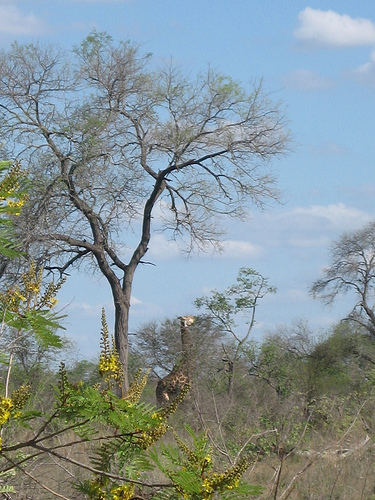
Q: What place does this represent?
A: It represents the field.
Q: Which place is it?
A: It is a field.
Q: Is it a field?
A: Yes, it is a field.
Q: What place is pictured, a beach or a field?
A: It is a field.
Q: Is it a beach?
A: No, it is a field.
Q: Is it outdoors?
A: Yes, it is outdoors.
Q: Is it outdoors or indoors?
A: It is outdoors.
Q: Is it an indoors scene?
A: No, it is outdoors.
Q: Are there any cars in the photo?
A: No, there are no cars.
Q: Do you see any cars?
A: No, there are no cars.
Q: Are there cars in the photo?
A: No, there are no cars.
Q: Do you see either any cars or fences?
A: No, there are no cars or fences.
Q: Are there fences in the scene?
A: No, there are no fences.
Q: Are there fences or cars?
A: No, there are no fences or cars.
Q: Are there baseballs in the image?
A: No, there are no baseballs.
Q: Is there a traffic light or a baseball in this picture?
A: No, there are no baseballs or traffic lights.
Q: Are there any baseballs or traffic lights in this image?
A: No, there are no baseballs or traffic lights.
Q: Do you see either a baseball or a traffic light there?
A: No, there are no baseballs or traffic lights.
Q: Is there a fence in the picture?
A: No, there are no fences.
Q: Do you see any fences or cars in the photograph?
A: No, there are no fences or cars.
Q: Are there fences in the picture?
A: No, there are no fences.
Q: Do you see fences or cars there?
A: No, there are no fences or cars.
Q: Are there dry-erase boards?
A: No, there are no dry-erase boards.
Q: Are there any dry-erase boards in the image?
A: No, there are no dry-erase boards.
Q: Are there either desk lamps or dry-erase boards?
A: No, there are no dry-erase boards or desk lamps.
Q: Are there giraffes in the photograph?
A: Yes, there is a giraffe.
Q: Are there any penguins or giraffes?
A: Yes, there is a giraffe.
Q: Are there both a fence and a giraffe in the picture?
A: No, there is a giraffe but no fences.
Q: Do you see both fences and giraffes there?
A: No, there is a giraffe but no fences.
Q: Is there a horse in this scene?
A: No, there are no horses.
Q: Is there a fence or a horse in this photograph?
A: No, there are no horses or fences.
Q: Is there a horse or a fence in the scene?
A: No, there are no horses or fences.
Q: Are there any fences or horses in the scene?
A: No, there are no horses or fences.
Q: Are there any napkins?
A: No, there are no napkins.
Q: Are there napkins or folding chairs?
A: No, there are no napkins or folding chairs.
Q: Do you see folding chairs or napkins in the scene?
A: No, there are no napkins or folding chairs.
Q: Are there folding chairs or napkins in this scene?
A: No, there are no napkins or folding chairs.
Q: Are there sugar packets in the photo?
A: No, there are no sugar packets.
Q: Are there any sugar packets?
A: No, there are no sugar packets.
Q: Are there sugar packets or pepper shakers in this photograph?
A: No, there are no sugar packets or pepper shakers.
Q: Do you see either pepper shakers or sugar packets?
A: No, there are no sugar packets or pepper shakers.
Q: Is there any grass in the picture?
A: Yes, there is grass.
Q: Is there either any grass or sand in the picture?
A: Yes, there is grass.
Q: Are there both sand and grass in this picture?
A: No, there is grass but no sand.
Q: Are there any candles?
A: No, there are no candles.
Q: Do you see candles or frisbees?
A: No, there are no candles or frisbees.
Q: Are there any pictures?
A: No, there are no pictures.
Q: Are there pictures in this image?
A: No, there are no pictures.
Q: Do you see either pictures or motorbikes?
A: No, there are no pictures or motorbikes.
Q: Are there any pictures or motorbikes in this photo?
A: No, there are no pictures or motorbikes.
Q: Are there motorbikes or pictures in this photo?
A: No, there are no pictures or motorbikes.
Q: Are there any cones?
A: No, there are no cones.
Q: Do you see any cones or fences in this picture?
A: No, there are no cones or fences.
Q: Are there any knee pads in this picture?
A: No, there are no knee pads.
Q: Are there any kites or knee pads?
A: No, there are no knee pads or kites.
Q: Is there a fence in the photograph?
A: No, there are no fences.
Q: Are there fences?
A: No, there are no fences.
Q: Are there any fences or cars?
A: No, there are no fences or cars.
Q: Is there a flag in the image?
A: No, there are no flags.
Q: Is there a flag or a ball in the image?
A: No, there are no flags or balls.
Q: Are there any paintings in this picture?
A: No, there are no paintings.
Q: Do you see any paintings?
A: No, there are no paintings.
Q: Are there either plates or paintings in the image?
A: No, there are no paintings or plates.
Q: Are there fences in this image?
A: No, there are no fences.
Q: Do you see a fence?
A: No, there are no fences.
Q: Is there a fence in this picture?
A: No, there are no fences.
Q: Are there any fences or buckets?
A: No, there are no fences or buckets.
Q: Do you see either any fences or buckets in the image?
A: No, there are no fences or buckets.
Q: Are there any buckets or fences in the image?
A: No, there are no fences or buckets.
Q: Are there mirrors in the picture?
A: No, there are no mirrors.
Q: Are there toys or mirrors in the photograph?
A: No, there are no mirrors or toys.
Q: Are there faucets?
A: No, there are no faucets.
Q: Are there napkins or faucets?
A: No, there are no faucets or napkins.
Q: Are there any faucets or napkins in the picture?
A: No, there are no faucets or napkins.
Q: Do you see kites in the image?
A: No, there are no kites.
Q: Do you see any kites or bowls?
A: No, there are no kites or bowls.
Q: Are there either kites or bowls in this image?
A: No, there are no kites or bowls.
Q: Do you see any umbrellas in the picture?
A: No, there are no umbrellas.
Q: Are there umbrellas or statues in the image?
A: No, there are no umbrellas or statues.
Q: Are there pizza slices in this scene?
A: No, there are no pizza slices.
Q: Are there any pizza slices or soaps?
A: No, there are no pizza slices or soaps.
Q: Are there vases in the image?
A: No, there are no vases.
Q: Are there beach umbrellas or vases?
A: No, there are no vases or beach umbrellas.